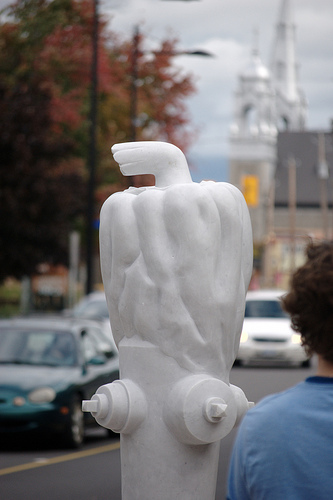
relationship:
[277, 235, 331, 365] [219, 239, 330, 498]
head part of person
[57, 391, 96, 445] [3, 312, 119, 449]
tire of car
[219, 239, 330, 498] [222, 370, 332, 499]
person in t-shirt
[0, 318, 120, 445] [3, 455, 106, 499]
car on street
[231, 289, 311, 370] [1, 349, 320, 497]
car on street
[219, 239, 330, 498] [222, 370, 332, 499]
person wearing t-shirt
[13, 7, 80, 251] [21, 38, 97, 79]
tree with leaves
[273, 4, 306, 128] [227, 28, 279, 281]
steeple behind tower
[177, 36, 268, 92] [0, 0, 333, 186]
cloud in sky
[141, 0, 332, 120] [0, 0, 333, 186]
cloud in sky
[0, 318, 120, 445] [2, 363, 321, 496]
car in street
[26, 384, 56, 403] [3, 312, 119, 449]
headlight of car